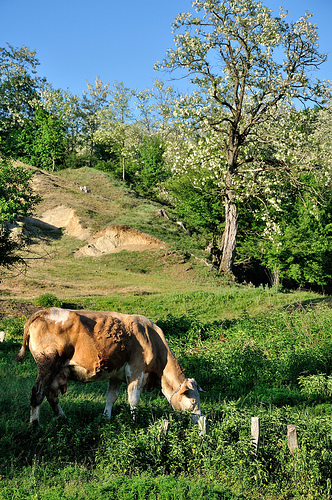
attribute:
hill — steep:
[77, 158, 165, 279]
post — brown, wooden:
[243, 413, 261, 463]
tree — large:
[172, 14, 309, 175]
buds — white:
[257, 20, 283, 43]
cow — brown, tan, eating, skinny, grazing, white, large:
[12, 305, 227, 449]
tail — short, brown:
[13, 314, 42, 365]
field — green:
[194, 274, 312, 378]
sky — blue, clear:
[54, 10, 155, 62]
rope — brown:
[163, 384, 194, 407]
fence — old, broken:
[198, 408, 317, 464]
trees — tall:
[144, 12, 331, 279]